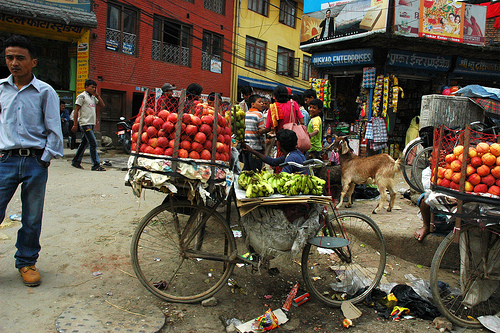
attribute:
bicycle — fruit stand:
[132, 147, 387, 307]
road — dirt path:
[49, 169, 127, 333]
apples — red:
[131, 107, 231, 161]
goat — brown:
[330, 138, 404, 215]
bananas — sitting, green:
[234, 166, 326, 200]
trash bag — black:
[376, 285, 436, 326]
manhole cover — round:
[54, 292, 166, 332]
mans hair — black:
[4, 33, 39, 59]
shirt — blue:
[1, 77, 63, 165]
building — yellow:
[235, 1, 313, 95]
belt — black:
[1, 149, 45, 157]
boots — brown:
[18, 265, 42, 288]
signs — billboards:
[303, 1, 389, 44]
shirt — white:
[73, 91, 99, 126]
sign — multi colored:
[419, 0, 467, 42]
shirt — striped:
[243, 107, 266, 151]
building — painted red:
[89, 1, 233, 81]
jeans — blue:
[1, 154, 49, 268]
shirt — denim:
[264, 151, 307, 170]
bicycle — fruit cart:
[126, 85, 385, 308]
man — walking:
[70, 80, 106, 173]